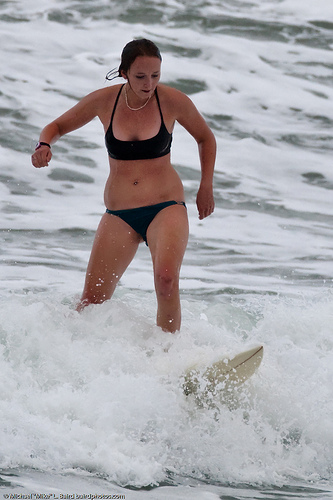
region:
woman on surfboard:
[23, 14, 309, 483]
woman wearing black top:
[79, 54, 193, 180]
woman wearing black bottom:
[89, 181, 201, 259]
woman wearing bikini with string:
[15, 29, 235, 339]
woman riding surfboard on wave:
[14, 22, 331, 493]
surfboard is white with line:
[8, 286, 324, 485]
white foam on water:
[209, 120, 329, 317]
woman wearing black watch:
[12, 121, 66, 169]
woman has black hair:
[89, 20, 165, 83]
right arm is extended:
[20, 78, 133, 191]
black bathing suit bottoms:
[99, 202, 199, 247]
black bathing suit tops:
[100, 112, 195, 173]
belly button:
[124, 175, 151, 187]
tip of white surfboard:
[180, 348, 290, 406]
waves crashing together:
[60, 352, 172, 462]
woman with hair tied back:
[91, 39, 188, 110]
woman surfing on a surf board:
[80, 31, 271, 394]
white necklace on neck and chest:
[115, 89, 160, 114]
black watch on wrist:
[29, 143, 58, 154]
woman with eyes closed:
[133, 49, 171, 115]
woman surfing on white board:
[27, 39, 209, 342]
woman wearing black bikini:
[20, 32, 227, 349]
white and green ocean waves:
[21, 363, 75, 420]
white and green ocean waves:
[119, 431, 155, 464]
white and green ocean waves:
[218, 415, 271, 473]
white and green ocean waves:
[250, 282, 287, 320]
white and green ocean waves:
[16, 269, 39, 296]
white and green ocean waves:
[248, 144, 283, 194]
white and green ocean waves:
[18, 210, 64, 239]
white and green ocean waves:
[237, 48, 275, 98]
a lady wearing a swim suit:
[31, 38, 215, 337]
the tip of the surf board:
[197, 349, 265, 399]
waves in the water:
[4, 313, 332, 479]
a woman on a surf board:
[33, 38, 264, 388]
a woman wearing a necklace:
[90, 38, 180, 161]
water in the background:
[216, 12, 332, 298]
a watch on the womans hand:
[33, 141, 51, 149]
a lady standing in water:
[37, 38, 255, 451]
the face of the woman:
[121, 46, 161, 99]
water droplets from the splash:
[91, 420, 168, 448]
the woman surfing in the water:
[31, 38, 263, 404]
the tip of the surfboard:
[176, 344, 262, 405]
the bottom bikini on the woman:
[104, 199, 186, 245]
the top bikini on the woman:
[103, 83, 171, 160]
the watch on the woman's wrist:
[34, 141, 50, 150]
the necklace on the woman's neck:
[123, 82, 152, 110]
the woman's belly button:
[132, 180, 138, 186]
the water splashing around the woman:
[1, 282, 331, 490]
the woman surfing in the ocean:
[31, 38, 263, 395]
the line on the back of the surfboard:
[222, 344, 263, 374]